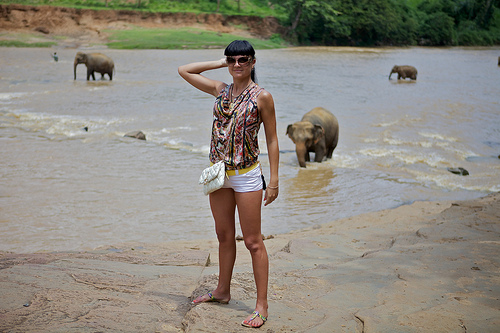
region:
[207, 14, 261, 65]
girl has black hair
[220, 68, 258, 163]
girl has brown shirt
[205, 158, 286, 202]
girl has white shorts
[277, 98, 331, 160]
small elephant behind girl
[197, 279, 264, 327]
girl is wearing sandals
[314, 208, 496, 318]
sand is light brown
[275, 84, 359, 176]
elephant is in water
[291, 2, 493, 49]
green trees on shore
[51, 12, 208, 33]
green and brown bank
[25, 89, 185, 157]
white wave on water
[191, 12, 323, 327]
a lady standing beside a river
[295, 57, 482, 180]
elephants are in water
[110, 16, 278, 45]
grasses are grown beside the river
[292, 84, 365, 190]
the elephant is walking in water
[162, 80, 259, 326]
the lady has a white handbag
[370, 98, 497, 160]
the water is calm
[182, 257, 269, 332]
the lady is wearing sandals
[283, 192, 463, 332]
the ground is made of soil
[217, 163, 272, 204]
the short is white in color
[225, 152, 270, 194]
the belt is yellow in color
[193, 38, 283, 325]
a woman posing for a phoograph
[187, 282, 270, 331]
a woman wearing fancy footwear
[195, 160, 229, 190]
woman holding white color handbag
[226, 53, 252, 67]
woman wearing sun glasses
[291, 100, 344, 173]
elephant in the water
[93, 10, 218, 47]
dirt with green grass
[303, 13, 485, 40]
lot of trees with its branches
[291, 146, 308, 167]
trunk of the elephant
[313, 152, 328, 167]
front leg of the elephant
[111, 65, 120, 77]
tail of the elephant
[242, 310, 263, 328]
woman wearing flat footwear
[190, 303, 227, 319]
woman standing on rock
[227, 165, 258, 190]
woman wearing white shorts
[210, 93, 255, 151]
woman wearing printed top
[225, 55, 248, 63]
woman wearing sun glasses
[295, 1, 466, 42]
trees visible at background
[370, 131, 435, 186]
waves created on water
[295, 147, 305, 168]
trunk of the elephant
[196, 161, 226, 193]
white color bag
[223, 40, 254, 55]
woman with black color hair